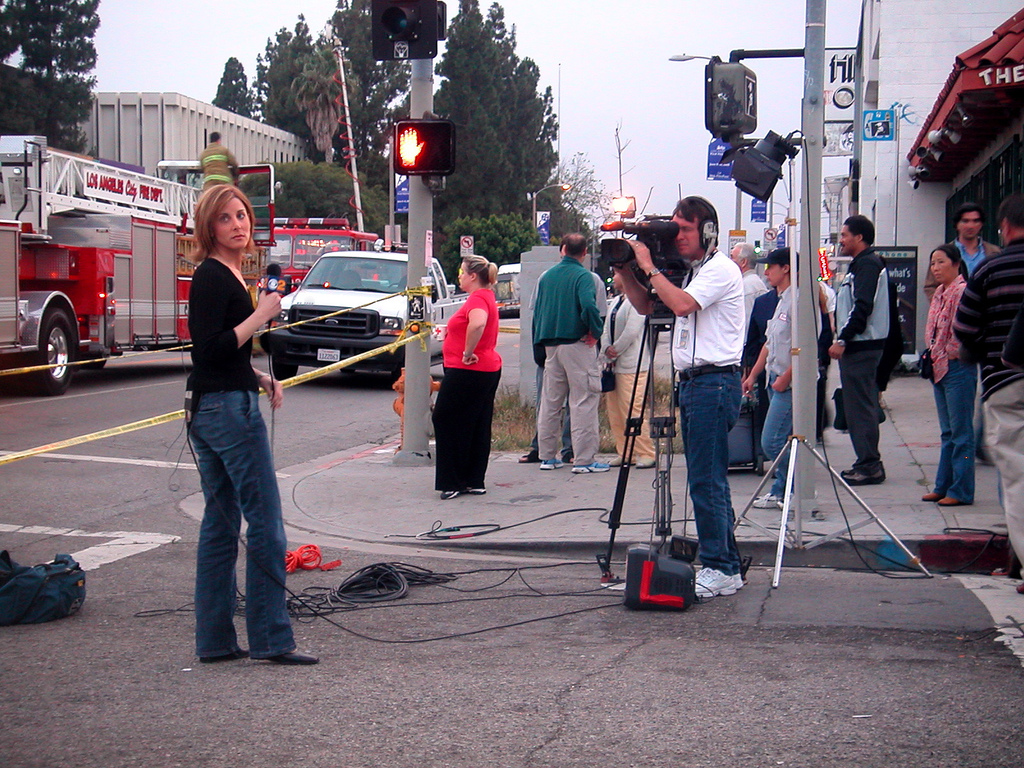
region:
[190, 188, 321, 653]
woman on the street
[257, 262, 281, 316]
microphone in the hand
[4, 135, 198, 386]
fire truck on road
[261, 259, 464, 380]
a truck is parked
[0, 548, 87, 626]
bag on the ground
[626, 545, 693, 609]
box on the ground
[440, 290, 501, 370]
the shirt is red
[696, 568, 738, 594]
the shoe is white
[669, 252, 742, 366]
the shirt is white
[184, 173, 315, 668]
Woman holding a microphone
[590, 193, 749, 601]
Photographer filming the woman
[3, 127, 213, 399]
Fire truck on the street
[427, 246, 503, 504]
Woman standing near the corner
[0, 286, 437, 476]
Yellow caution tape across the street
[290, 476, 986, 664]
Electronic wires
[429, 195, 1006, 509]
People standing on the sidewalk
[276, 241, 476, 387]
Truck on the road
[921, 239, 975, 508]
Woman wearing a pink sweater and blue jeans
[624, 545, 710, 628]
red tape on bag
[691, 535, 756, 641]
pair of white sneakers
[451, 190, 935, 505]
people standing on sidewalk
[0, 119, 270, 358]
red fire truck on street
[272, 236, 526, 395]
white van driving down the street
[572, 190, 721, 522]
black camera on stand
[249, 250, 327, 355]
black padded mic in woman's hand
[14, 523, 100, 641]
blue bag in street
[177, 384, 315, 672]
Woman wearing pants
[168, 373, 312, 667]
Woman is wearing pants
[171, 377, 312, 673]
Woman wearing blue pants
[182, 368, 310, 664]
Woman is wearing blue pants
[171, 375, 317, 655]
Woman wearing jeans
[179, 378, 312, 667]
Woman is wearing jeans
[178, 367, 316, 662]
Woman wearing blue jeans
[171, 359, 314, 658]
Woman is wearing blue jeans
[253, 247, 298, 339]
Woman holding a microphone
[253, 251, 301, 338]
Woman is holding a microphone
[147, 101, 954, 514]
many people on the street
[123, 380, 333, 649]
pants on the lady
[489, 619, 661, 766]
crack on the sidewalk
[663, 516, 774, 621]
shoes on man's feet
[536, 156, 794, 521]
man on a camera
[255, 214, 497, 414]
truck on the street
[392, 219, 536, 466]
lady in light colored shirt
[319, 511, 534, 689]
cord on the street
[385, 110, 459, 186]
sign indicates no crossing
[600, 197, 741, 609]
camera man at work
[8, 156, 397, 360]
two red fire trucks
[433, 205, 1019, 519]
people standing on sidewalk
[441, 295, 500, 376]
The red shirt the woman is wearing.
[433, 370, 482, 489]
The black pants the woman in the red shirt is wearing.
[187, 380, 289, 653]
The jeans the news reporter is wearing.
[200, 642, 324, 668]
The black shoes the news reporter is wearing.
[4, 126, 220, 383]
The fire truck in the front of the street.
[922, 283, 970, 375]
The pink scarf the woman is wearing.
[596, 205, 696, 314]
The camera the man is using to record the news reporter.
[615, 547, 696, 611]
The red and black television on the ground.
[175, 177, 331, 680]
the reporter is not looking into the camera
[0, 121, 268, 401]
a hook and latter fire truck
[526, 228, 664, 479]
these people are having a discussion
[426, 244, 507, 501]
this woman is watching the fire fighters